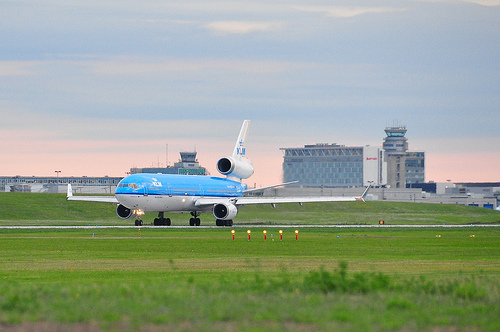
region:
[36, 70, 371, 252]
a plane on the runway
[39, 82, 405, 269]
a blue and white airplane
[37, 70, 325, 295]
an airplane on the ground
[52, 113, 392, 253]
a blue and white airplane on the ground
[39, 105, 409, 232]
a large airplane on the runway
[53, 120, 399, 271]
a passenger plane on the ground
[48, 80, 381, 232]
an airplane on the runway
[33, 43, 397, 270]
an airplane on the road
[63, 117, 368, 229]
blue and white plane on runway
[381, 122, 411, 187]
airport tower in background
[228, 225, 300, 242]
red posts with lights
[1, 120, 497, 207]
airport in background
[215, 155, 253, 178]
large engine on tail of plane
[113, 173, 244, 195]
blue top half of plane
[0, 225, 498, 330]
field of grass next to runway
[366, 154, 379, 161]
red lettering on side of airport building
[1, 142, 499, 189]
patch of pink in lower section of sky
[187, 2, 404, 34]
small white wispy clouds in sky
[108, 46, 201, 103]
white clouds in the sky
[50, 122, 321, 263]
blue and white plane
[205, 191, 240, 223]
engine on side of plane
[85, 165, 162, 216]
front of the plane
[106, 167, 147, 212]
nose of the plane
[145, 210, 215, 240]
wheels on the plane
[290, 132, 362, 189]
building in the background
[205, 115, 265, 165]
tail of the plane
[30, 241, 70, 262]
grass next to the plane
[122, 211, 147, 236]
front tire of the plane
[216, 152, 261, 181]
the engine of a plane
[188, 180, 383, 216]
the wing of a plane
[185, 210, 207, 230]
the wheel of a plane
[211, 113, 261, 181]
the tail of a plane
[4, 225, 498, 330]
a grassy green field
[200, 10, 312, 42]
a cloud in the sky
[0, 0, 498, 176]
a blue and pink sky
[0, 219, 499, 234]
a gray runway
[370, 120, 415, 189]
an air control tower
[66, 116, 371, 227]
a blue and white airplane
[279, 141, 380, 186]
a large building in distance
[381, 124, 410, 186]
a tall airport tower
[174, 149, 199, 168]
an airport tower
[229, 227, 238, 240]
a small red warning light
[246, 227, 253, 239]
a small red warning light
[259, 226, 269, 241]
a small red warning light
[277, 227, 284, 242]
a small red warning light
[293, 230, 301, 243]
a small red warning light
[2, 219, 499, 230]
a paved airport runway